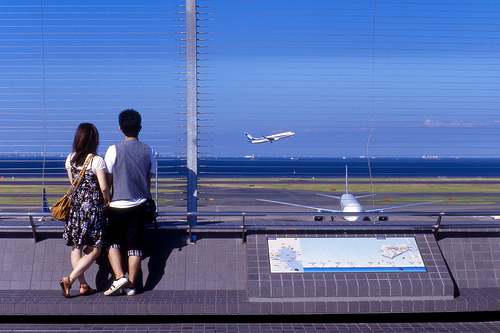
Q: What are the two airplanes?
A: Shown.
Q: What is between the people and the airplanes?
A: The fence.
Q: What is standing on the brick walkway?
A: The people.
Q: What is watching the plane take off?
A: The young man.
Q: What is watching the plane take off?
A: The young woman.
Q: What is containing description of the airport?
A: The map.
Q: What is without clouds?
A: Blue sky.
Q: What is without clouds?
A: Blue sky.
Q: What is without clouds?
A: Blue sky.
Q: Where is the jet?
A: On the tarmac.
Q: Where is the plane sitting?
A: On the runway.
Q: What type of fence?
A: Wire.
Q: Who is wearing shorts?
A: The man.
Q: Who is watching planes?
A: A couple.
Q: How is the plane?
A: Resting on tarmac.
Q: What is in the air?
A: Plane.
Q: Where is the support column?
A: Beside the couple.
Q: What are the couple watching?
A: Planes take off.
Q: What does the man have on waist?
A: A jacket.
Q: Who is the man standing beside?
A: A woman in a flower dress.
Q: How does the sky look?
A: Crystal blue.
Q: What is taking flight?
A: A plane.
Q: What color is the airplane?
A: White.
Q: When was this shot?
A: Daytime.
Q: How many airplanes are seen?
A: 2.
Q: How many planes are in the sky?
A: 1.